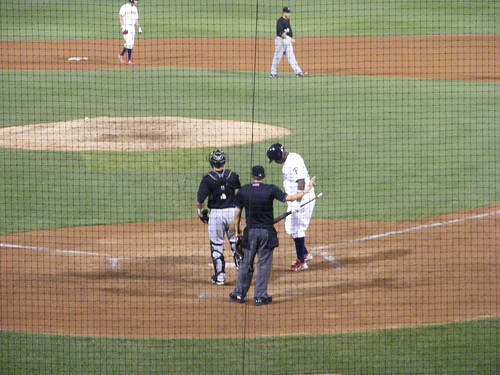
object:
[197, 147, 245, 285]
catcher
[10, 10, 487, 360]
baseball game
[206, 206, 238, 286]
pants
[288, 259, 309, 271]
shoes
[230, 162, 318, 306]
man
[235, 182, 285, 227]
shirt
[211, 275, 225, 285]
feet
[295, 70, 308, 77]
feet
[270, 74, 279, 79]
feet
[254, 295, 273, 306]
feet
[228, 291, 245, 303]
feet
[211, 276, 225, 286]
feet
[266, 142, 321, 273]
man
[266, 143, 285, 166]
helmet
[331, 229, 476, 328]
dirt ground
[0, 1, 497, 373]
grass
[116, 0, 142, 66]
man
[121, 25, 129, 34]
glove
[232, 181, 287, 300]
umpire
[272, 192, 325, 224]
bat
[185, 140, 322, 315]
pitcher's mound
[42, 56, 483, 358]
baseball field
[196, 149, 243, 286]
man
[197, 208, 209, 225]
baseball glove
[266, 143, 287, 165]
head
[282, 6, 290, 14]
head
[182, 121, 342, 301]
players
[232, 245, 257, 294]
leg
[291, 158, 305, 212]
arm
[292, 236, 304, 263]
black socks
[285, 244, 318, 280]
cleats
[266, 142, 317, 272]
baseball player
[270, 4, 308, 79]
man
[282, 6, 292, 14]
hat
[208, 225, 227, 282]
leg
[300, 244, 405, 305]
shadows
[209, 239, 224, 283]
home plate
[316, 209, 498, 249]
chalk line